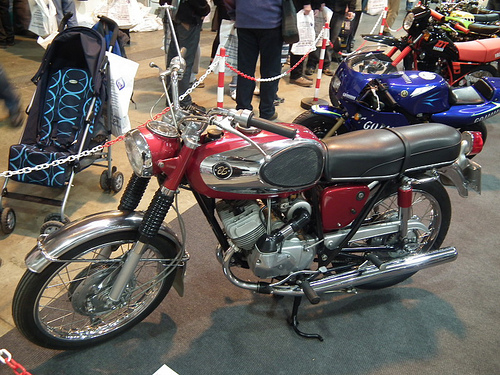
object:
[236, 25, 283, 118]
pants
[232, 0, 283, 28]
shirt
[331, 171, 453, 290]
wheel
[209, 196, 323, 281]
engine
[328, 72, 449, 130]
engine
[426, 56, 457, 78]
engine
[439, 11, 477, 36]
engine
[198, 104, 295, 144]
handlebar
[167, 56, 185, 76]
handlebar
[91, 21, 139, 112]
backpack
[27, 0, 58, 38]
bags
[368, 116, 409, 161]
ground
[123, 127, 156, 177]
headlight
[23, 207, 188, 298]
silver cover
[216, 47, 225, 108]
pole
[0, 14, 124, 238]
stroller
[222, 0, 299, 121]
people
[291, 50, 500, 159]
blue motorcycle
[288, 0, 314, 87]
person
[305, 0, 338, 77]
person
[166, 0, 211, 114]
person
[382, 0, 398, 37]
person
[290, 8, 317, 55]
bag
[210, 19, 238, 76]
bag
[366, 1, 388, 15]
bag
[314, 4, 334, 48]
bag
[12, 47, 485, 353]
bike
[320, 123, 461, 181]
seat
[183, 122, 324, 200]
gas tank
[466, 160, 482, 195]
license plate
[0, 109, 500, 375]
carpeting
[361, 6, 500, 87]
motorcycle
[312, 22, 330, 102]
poles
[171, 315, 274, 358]
ground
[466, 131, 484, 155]
tail light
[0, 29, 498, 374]
floor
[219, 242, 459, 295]
exhaust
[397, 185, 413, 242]
rear shock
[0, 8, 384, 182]
chain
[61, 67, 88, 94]
circles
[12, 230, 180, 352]
front wheel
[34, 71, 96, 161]
writing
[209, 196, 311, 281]
dt